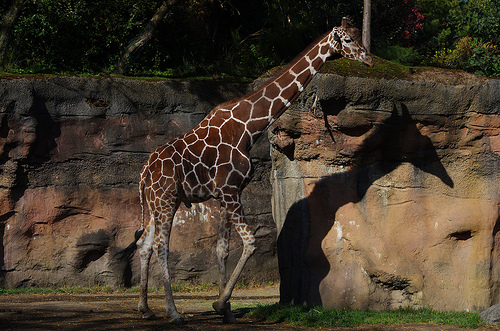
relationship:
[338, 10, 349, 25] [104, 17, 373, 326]
horns on giraffe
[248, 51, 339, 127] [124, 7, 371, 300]
neck of giraffe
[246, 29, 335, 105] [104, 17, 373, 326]
mane of giraffe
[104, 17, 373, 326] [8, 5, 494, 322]
giraffe in zoo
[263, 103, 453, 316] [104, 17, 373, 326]
shadow of giraffe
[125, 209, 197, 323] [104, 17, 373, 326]
legs of giraffe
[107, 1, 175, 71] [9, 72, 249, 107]
tree growing on top of rock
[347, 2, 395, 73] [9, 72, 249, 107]
tree growing on top of rock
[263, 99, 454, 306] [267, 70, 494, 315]
shadow on rock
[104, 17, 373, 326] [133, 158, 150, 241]
giraffe has tail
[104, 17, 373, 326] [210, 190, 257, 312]
giraffe has front legs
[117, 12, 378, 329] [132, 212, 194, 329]
giraffe has legs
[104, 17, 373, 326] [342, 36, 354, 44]
giraffe has eye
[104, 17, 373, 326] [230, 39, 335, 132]
giraffe has neck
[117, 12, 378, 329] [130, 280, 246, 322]
giraffe has feet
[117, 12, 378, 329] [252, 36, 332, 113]
giraffe has neck